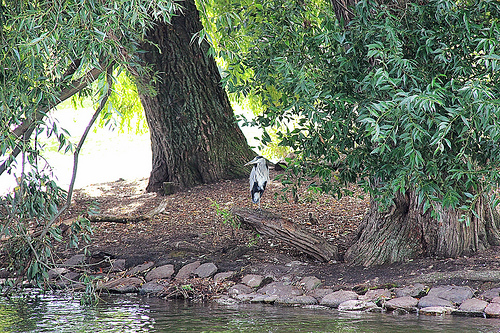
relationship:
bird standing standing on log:
[231, 122, 293, 219] [232, 203, 341, 266]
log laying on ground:
[230, 207, 345, 267] [1, 174, 499, 314]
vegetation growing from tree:
[330, 34, 497, 225] [368, 37, 471, 198]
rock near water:
[320, 290, 358, 309] [103, 266, 216, 331]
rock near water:
[190, 258, 220, 280] [34, 298, 339, 330]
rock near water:
[337, 297, 377, 312] [0, 272, 497, 332]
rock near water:
[295, 266, 329, 290] [35, 308, 497, 330]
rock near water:
[100, 273, 144, 294] [36, 302, 332, 331]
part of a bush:
[354, 122, 381, 154] [285, 7, 499, 223]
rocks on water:
[4, 250, 494, 315] [0, 297, 489, 330]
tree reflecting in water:
[0, 2, 274, 304] [0, 280, 494, 330]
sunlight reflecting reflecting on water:
[28, 291, 155, 331] [0, 272, 497, 332]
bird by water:
[242, 155, 271, 204] [125, 298, 189, 323]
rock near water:
[192, 261, 220, 283] [0, 280, 494, 330]